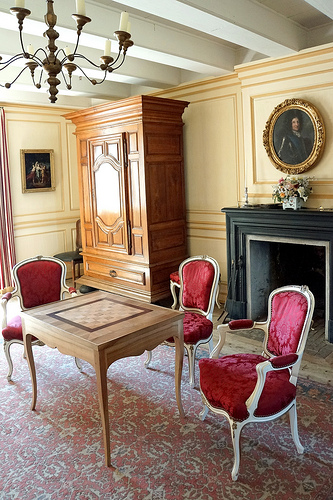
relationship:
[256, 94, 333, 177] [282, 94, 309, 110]
picture has gold frame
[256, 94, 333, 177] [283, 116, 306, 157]
picture of man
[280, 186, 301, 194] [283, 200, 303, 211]
flowers in vase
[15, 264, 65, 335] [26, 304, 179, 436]
chair by checkers table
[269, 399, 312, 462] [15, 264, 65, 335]
leg of chair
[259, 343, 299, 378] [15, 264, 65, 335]
arm of chair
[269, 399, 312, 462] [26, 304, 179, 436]
leg of checkers table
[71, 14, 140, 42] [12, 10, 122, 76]
candles of chandelier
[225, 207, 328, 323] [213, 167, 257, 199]
fireplace on wall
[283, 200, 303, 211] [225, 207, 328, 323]
vase on fireplace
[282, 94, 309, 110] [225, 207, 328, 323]
gold frame above fireplace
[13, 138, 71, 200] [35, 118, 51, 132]
square frame on wall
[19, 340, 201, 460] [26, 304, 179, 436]
legs of checkers table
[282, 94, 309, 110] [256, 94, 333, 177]
gold frame of picture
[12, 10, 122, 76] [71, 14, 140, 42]
chandelier with candles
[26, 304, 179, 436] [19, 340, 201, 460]
checkers table has legs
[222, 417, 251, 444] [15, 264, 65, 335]
gold leaf on chair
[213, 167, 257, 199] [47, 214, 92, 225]
wall with gold trim